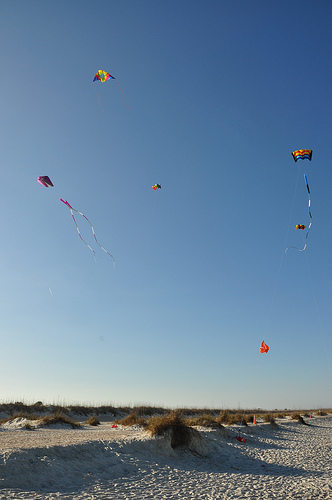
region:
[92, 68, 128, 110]
A triangular tie-dye kite with white ribbons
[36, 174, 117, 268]
A purple kite with long striped ribbons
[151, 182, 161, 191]
A rainbow-striped, parachute-shaped kite in the distance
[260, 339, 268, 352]
An orange kite low to the ground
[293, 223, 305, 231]
A multicolored parachute-shaped kite in the distance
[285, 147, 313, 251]
A multicolored kite with a long striped ribbon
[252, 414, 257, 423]
An orange traffic cone in the sand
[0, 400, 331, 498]
A sandy, grassy riverbank or shore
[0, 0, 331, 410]
A clear blue sky full of kites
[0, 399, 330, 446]
Tufts of dark grass in the sand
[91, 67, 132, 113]
multi-color kite flying highest in the sky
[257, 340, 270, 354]
orange kite flying low to the ground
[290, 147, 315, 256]
multi-color kite with a long tail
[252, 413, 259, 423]
an orange cone sitting on the sand dune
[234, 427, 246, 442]
a person sitting in front of the sand dune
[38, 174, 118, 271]
a pink and white kite with a long tail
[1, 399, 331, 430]
the dunes at the beach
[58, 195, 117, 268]
the pink and white striped tail of a kite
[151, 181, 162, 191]
a multi-color kite in the middle of all the kites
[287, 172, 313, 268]
blue black and white tail of a multi-color kite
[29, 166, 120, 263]
a kite with long tails.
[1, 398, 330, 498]
a wild grass covered sandy beach.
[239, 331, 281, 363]
an orange kite in the sky.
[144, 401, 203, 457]
a wild green bush.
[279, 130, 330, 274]
a kite with a long tail.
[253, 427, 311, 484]
a section of beach with foot prints.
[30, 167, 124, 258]
a colorful kite.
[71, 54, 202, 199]
a rainbow colored kite.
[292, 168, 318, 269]
a long tail on a kite.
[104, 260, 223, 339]
a section of clear blue sky.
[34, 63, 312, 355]
six kites in the sky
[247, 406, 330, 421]
two caution cones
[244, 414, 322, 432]
caution cones are orange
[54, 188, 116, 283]
kite has white and purple streamers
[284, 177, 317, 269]
kite has a blue and white tail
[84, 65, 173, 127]
kite has two red streamers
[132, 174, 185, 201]
kite is multi colored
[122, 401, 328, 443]
grass along the beach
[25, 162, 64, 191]
kite is purple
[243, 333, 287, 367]
kite is orange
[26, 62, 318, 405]
several kites in the sky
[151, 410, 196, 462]
plants growing in the sand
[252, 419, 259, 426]
something orange on the sand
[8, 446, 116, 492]
shadow on the sand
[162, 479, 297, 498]
sand is not smooth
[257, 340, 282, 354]
orange kite in the sky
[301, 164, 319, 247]
long tail of the kite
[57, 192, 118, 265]
two purple and white tails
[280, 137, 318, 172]
rainbow kite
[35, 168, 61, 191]
purple body of the kite